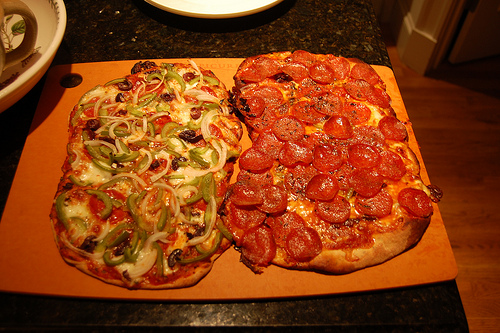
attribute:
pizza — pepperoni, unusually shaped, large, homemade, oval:
[213, 50, 444, 275]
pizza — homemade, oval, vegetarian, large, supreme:
[47, 59, 244, 290]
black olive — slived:
[131, 61, 144, 74]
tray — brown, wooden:
[0, 56, 459, 302]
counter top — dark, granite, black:
[0, 0, 468, 332]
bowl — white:
[0, 0, 67, 114]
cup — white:
[1, 1, 39, 71]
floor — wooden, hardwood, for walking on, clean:
[379, 19, 499, 333]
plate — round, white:
[143, 0, 285, 19]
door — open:
[446, 1, 500, 68]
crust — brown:
[271, 214, 432, 275]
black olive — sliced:
[178, 128, 196, 139]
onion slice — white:
[210, 138, 228, 172]